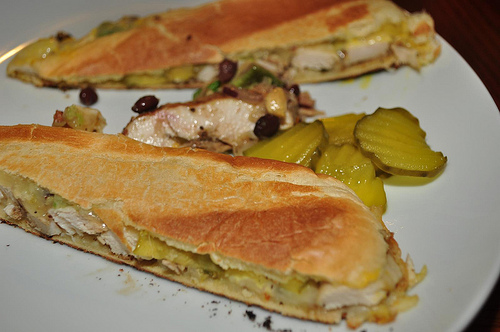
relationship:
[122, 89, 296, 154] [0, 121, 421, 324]
chicken in between piece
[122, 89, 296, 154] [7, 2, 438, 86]
chicken in between piece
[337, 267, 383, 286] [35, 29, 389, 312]
cheese on sandwich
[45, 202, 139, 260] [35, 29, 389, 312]
chicken on sandwich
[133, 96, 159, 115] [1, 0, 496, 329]
caper sprinkled on plate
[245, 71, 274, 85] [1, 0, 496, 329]
caper sprinkled on plate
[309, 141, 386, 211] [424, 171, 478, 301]
pickle on plate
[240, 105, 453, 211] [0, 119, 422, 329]
pickle slices between sandwich half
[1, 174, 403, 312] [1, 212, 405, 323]
food in bread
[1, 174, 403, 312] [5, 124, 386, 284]
food in bread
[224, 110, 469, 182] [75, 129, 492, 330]
chips near sandwich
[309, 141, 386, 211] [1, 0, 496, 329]
pickle on plate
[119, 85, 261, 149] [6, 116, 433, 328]
meat on a sandwich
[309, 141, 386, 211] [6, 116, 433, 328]
pickle on a sandwich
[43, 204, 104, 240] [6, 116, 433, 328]
meat on a sandwich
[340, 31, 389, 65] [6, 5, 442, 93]
meat on a sandwich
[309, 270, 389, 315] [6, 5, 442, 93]
meat on a sandwich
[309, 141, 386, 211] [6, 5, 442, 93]
pickle on a sandwich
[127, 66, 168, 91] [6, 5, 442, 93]
pickles on a sandwich